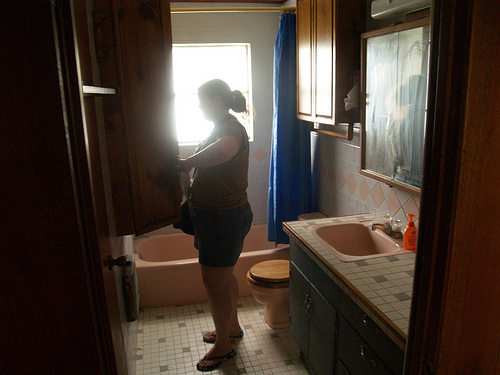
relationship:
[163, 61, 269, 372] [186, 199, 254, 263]
lady wearing shorts